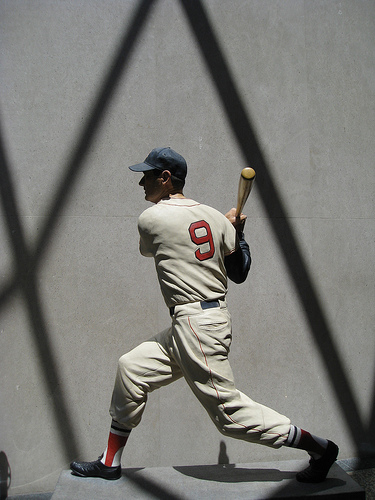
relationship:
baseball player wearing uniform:
[66, 153, 339, 484] [111, 191, 300, 452]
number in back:
[187, 217, 215, 263] [146, 193, 225, 313]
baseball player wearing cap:
[66, 153, 339, 484] [129, 147, 187, 175]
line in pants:
[105, 428, 119, 464] [110, 305, 301, 448]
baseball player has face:
[66, 153, 339, 484] [138, 170, 161, 208]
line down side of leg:
[105, 428, 119, 464] [101, 330, 182, 466]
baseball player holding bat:
[66, 153, 339, 484] [235, 166, 254, 224]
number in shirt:
[187, 217, 215, 263] [136, 189, 238, 306]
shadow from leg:
[122, 460, 171, 499] [101, 330, 182, 466]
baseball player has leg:
[66, 153, 339, 484] [198, 354, 341, 474]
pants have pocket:
[110, 305, 301, 448] [206, 320, 232, 356]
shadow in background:
[4, 1, 369, 491] [23, 10, 371, 500]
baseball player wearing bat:
[66, 153, 339, 484] [235, 166, 254, 224]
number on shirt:
[187, 217, 215, 263] [136, 189, 238, 306]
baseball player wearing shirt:
[66, 153, 339, 484] [136, 189, 238, 306]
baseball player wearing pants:
[66, 153, 339, 484] [110, 305, 301, 448]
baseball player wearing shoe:
[66, 153, 339, 484] [299, 438, 338, 485]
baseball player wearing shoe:
[66, 153, 339, 484] [68, 460, 125, 481]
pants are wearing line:
[110, 305, 301, 448] [105, 428, 119, 464]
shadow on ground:
[122, 460, 171, 499] [10, 269, 358, 497]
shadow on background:
[122, 460, 171, 499] [23, 10, 371, 500]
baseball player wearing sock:
[66, 153, 339, 484] [99, 426, 130, 467]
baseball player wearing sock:
[66, 153, 339, 484] [285, 423, 301, 446]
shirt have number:
[136, 189, 238, 306] [187, 217, 215, 263]